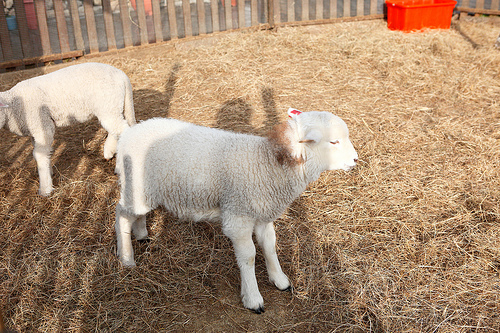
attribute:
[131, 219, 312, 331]
hay — brown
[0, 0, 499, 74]
fence — wooden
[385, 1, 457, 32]
plastic container — orange, bright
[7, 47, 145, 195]
sheep — white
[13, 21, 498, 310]
hay — brown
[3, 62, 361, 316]
sheep — white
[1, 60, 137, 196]
sheep — white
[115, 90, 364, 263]
sheep — white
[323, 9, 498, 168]
straw — fresh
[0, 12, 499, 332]
hay — brown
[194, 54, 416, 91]
hay — brown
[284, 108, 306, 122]
ear tag — red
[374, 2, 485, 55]
bin — orange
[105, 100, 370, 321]
lamb — white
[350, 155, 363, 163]
nose — black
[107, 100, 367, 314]
sheep — white